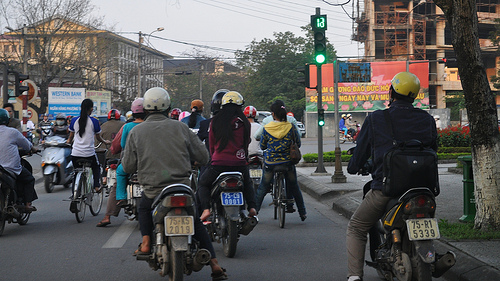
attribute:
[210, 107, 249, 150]
hair — black, long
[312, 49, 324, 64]
light — green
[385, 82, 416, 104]
helmet — yellow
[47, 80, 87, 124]
sign — white, blue, for bank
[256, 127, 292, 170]
hoodie — blue, yellow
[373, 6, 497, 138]
building — under construction, yellow, white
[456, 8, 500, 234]
tree — painted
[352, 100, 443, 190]
jacket — black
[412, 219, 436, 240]
license — on motorcycle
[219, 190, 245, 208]
plate — blue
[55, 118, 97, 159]
shirt — blue, white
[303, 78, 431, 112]
sign — yellow, pink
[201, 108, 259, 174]
sweater — burgundy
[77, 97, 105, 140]
hair — long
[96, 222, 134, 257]
line — white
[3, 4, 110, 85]
tree — bare